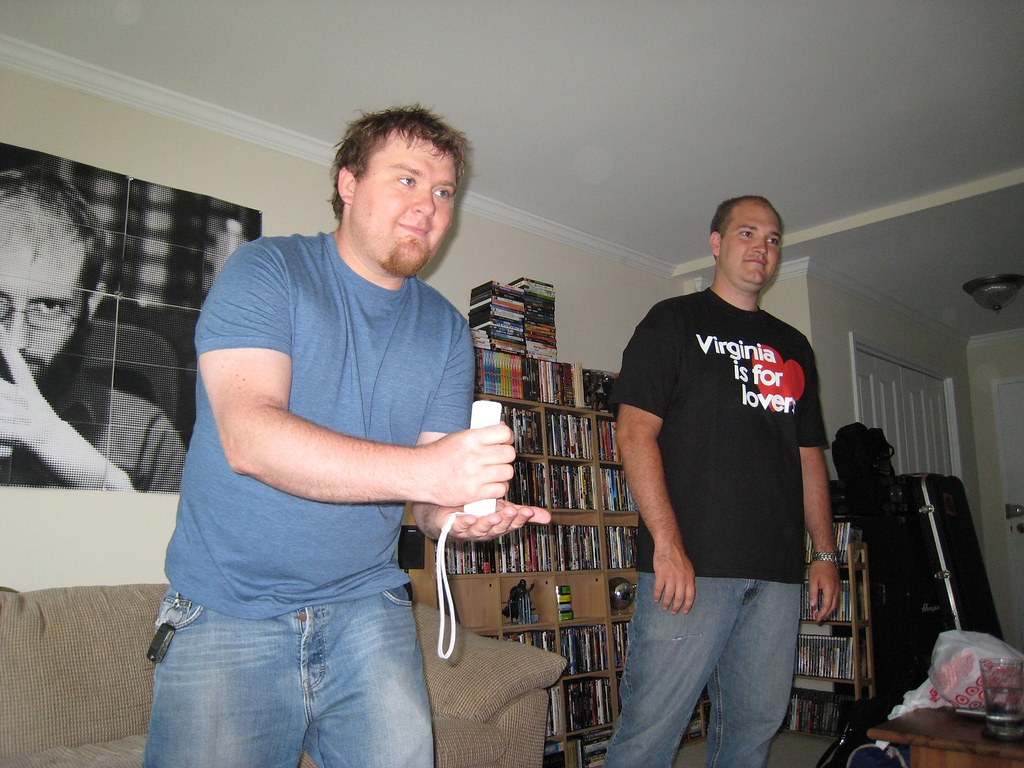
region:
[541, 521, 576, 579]
video on the shelf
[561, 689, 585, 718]
video on the shelf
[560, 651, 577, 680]
video on the shelf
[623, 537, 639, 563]
video on the shelf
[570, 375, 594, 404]
video on the shelf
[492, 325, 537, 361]
video on the shelf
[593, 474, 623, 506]
video on the shelf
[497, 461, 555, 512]
video on the shelf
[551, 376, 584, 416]
video on the shelf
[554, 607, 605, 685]
video on the shelf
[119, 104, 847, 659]
these are two men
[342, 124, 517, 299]
the man has a goatee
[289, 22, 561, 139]
the man has short hair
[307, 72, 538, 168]
the man's hair is brown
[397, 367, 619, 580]
the controller is white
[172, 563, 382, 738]
the man has blue jeans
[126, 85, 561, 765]
man is wearing a blue shirt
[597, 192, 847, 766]
man is wearing a black shirt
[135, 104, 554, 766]
man has a beard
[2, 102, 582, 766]
couch is behind the man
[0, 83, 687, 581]
picture is on the wall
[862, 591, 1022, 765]
bag is on the table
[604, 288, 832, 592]
logo is on the black shirt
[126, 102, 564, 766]
man is holding a game controller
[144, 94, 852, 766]
man is wearing jeans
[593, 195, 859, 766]
man is wearing a watch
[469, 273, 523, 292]
book stacked on the wood shelf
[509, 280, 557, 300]
book stacked on the wood shelf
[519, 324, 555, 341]
book stacked on the wood shelf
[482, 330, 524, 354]
book stacked on the wood shelf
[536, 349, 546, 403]
book stacked on the wood shelf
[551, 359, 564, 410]
book stacked on the wood shelf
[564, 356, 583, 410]
book stacked on the wood shelf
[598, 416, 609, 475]
book stacked on the wood shelf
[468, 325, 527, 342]
book stacked on the wood shelf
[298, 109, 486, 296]
the head of a man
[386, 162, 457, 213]
the eye of a man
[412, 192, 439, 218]
the nose of a man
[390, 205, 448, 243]
the mouth of a man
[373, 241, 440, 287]
the chin of a man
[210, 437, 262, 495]
the elbow of a man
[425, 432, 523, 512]
the hand of a man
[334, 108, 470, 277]
man with goatee on chin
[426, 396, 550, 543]
game control on hand palm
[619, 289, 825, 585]
white words on black shirt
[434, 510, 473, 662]
hanging white handle of control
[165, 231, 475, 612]
short sleeved tee shirt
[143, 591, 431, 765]
front of worn blue jeans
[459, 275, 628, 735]
rows of media on shelves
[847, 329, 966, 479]
closed white double doors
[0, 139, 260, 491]
poster of man's face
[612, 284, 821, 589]
Black shirt on a man.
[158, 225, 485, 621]
Blue shirt on a man.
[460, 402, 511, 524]
White Wii remote in a man's hand.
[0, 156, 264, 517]
Picture of a man on a wall.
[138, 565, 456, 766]
Blue jeans on a man.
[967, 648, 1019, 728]
Glass on a table.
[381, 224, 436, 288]
Beard on a man's face.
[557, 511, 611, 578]
a movie on the shelf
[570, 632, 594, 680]
a movie on the shelf